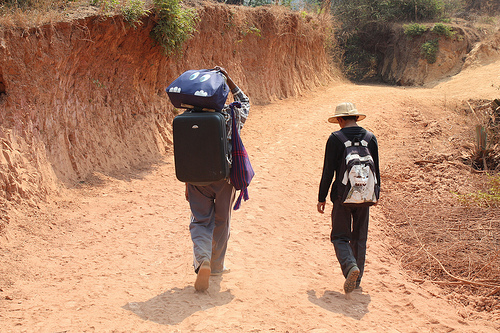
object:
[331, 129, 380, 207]
black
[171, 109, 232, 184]
black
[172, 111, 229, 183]
suitcase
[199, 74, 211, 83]
eyes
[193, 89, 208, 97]
hands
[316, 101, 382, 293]
person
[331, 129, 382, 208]
bag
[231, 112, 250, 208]
red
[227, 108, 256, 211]
bag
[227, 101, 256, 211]
blue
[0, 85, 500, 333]
dirt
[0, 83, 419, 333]
pathway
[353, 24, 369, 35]
plants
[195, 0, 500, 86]
distance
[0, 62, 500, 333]
ground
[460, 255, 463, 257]
sticks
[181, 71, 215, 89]
face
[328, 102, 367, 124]
tan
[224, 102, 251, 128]
shoulder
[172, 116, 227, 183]
shell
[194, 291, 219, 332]
tread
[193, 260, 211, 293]
boot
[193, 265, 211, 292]
rubber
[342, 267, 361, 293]
soles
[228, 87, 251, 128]
sleave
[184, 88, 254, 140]
shirt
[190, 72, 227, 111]
head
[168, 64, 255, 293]
people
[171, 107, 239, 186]
back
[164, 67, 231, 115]
bag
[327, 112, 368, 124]
brim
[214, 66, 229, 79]
hands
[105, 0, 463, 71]
vegetatiom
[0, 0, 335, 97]
ledge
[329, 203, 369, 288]
pamts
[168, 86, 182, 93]
feet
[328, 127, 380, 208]
back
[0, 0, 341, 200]
cliff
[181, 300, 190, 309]
shadows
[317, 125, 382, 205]
shirt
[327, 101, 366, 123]
hat